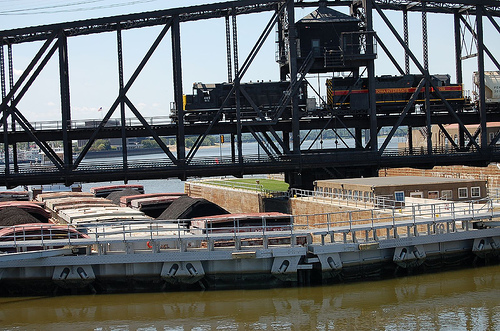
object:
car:
[88, 199, 140, 244]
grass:
[200, 177, 286, 190]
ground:
[361, 142, 379, 164]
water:
[16, 132, 430, 193]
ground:
[400, 205, 439, 250]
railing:
[0, 197, 499, 255]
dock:
[0, 195, 499, 297]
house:
[280, 3, 377, 74]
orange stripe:
[379, 85, 464, 95]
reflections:
[50, 287, 324, 318]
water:
[4, 261, 496, 329]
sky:
[3, 9, 498, 183]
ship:
[82, 145, 168, 159]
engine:
[167, 79, 309, 124]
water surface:
[161, 275, 498, 330]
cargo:
[0, 182, 313, 272]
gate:
[3, 212, 313, 293]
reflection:
[154, 307, 446, 325]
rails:
[290, 185, 372, 210]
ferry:
[0, 163, 498, 295]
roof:
[317, 175, 487, 186]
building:
[312, 174, 488, 207]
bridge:
[0, 0, 499, 189]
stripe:
[329, 85, 461, 95]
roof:
[292, 7, 357, 22]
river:
[0, 273, 498, 331]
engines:
[324, 72, 466, 118]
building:
[396, 123, 495, 158]